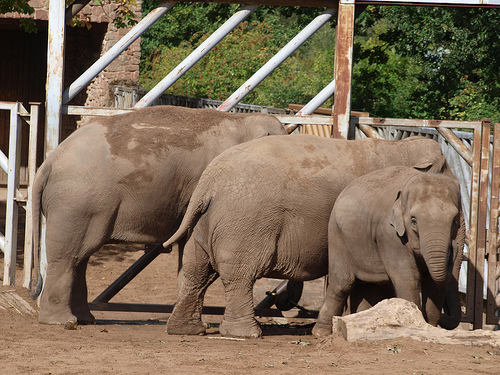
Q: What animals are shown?
A: Elephants.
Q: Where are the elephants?
A: In a zoo.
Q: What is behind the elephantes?
A: A fence.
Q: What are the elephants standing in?
A: Dirt.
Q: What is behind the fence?
A: A tree.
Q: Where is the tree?
A: Behind the fence.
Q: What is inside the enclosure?
A: Three elephants.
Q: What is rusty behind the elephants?
A: A metal gate.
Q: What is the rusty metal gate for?
A: It is for an elephant enclosure.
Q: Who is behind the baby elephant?
A: An adult elephant.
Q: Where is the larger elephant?
A: At the end of the line.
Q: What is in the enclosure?
A: There are elephants in the enclosure.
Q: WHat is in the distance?
A: Green trees.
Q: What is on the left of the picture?
A: A brick structure.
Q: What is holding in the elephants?
A: A wooden fence.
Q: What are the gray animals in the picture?
A: Elephants.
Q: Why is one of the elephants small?
A: It is a baby.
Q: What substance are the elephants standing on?
A: Dirt.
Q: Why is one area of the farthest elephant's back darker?
A: It is wet from mud.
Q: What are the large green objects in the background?
A: Trees.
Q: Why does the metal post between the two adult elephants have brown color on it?
A: It is rusted.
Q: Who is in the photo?
A: No one.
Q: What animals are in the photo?
A: Elephants.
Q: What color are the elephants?
A: Brown.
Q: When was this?
A: Daytime.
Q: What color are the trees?
A: Green.